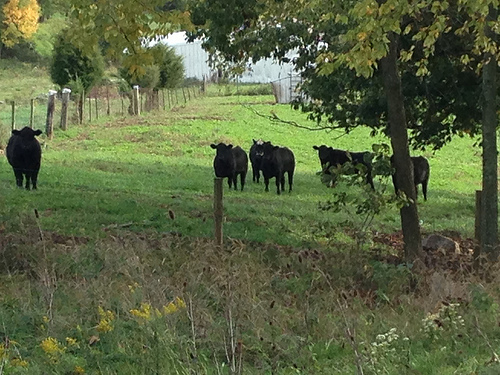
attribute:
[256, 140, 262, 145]
spot — white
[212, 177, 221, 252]
fence post — wooden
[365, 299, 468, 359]
flowers — white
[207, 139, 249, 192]
cow — black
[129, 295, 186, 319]
flowers — yellowish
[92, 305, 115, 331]
flowers — yellowish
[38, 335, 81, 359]
flowers — yellowish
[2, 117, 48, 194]
cow — black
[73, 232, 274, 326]
leaves — yellow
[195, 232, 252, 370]
plants — dired up